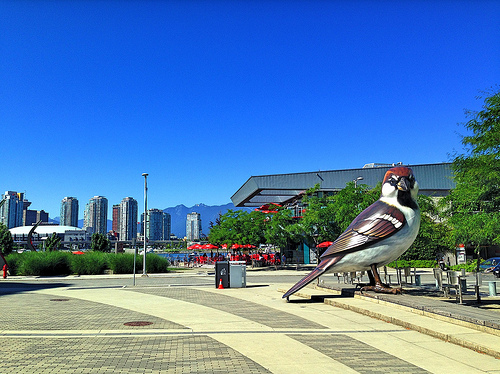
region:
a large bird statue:
[278, 151, 453, 318]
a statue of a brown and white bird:
[285, 146, 429, 305]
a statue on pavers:
[280, 161, 486, 366]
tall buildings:
[8, 175, 206, 262]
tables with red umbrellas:
[161, 229, 307, 281]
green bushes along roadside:
[11, 247, 205, 281]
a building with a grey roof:
[244, 152, 499, 242]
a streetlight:
[127, 167, 168, 297]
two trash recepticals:
[200, 252, 302, 310]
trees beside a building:
[219, 167, 491, 262]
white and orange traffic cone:
[202, 272, 229, 298]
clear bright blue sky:
[119, 39, 342, 137]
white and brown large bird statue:
[261, 180, 445, 283]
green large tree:
[453, 84, 493, 276]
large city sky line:
[4, 182, 195, 244]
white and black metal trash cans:
[200, 254, 269, 300]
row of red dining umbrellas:
[190, 233, 286, 270]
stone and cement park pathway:
[46, 294, 249, 362]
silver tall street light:
[123, 155, 185, 281]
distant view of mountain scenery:
[172, 182, 234, 219]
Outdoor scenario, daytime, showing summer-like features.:
[11, 8, 492, 370]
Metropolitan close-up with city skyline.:
[2, 15, 495, 371]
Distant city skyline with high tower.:
[7, 167, 182, 256]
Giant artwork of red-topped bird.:
[290, 166, 435, 299]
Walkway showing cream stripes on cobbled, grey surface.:
[13, 271, 475, 372]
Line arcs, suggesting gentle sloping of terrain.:
[73, 281, 365, 372]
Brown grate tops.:
[52, 293, 162, 339]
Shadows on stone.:
[24, 288, 176, 370]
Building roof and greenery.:
[226, 110, 498, 260]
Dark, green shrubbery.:
[20, 246, 160, 283]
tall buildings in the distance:
[2, 188, 209, 248]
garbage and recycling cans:
[212, 257, 248, 290]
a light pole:
[138, 168, 155, 281]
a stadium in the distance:
[3, 216, 93, 250]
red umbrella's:
[186, 240, 216, 267]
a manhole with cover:
[118, 313, 158, 330]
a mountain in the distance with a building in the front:
[152, 201, 235, 245]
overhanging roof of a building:
[225, 166, 315, 213]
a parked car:
[478, 253, 498, 273]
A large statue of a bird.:
[266, 151, 431, 312]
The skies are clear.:
[35, 15, 351, 170]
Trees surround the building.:
[200, 187, 490, 267]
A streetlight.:
[130, 165, 155, 285]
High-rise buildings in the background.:
[5, 180, 201, 240]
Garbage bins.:
[210, 257, 250, 287]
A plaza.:
[1, 266, 496, 366]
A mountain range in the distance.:
[52, 178, 268, 246]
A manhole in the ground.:
[115, 305, 150, 330]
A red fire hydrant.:
[0, 250, 20, 291]